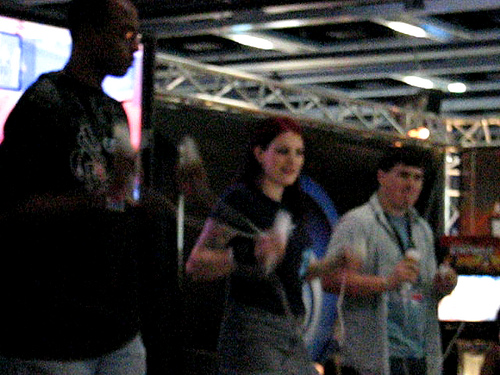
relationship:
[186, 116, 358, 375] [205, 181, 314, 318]
lady wears shirt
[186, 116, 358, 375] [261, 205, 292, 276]
lady playing with wii remote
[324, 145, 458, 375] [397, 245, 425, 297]
person playing controller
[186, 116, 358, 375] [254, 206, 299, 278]
lady holding controller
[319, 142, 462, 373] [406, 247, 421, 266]
person holding remote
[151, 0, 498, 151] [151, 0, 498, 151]
metal frame reinforced metal frame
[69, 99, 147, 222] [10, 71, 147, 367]
brandings on shirt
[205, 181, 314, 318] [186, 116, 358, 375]
shirt worn by lady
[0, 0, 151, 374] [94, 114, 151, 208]
person playing wii